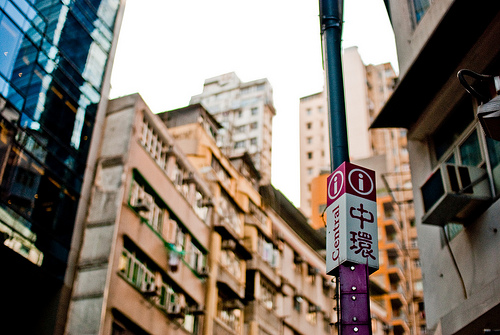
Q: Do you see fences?
A: No, there are no fences.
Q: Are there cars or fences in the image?
A: No, there are no fences or cars.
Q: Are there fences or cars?
A: No, there are no fences or cars.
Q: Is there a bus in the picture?
A: No, there are no buses.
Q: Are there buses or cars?
A: No, there are no buses or cars.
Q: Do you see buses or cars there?
A: No, there are no buses or cars.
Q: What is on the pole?
A: The sign is on the pole.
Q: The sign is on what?
A: The sign is on the pole.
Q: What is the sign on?
A: The sign is on the pole.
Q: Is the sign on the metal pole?
A: Yes, the sign is on the pole.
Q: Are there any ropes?
A: No, there are no ropes.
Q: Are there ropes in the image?
A: No, there are no ropes.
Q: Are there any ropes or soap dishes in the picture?
A: No, there are no ropes or soap dishes.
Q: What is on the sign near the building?
A: The symbol is on the sign.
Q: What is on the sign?
A: The symbol is on the sign.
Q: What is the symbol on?
A: The symbol is on the sign.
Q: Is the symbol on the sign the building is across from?
A: Yes, the symbol is on the sign.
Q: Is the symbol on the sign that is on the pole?
A: Yes, the symbol is on the sign.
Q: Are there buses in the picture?
A: No, there are no buses.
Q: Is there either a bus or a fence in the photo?
A: No, there are no buses or fences.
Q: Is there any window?
A: Yes, there are windows.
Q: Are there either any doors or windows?
A: Yes, there are windows.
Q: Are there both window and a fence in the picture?
A: No, there are windows but no fences.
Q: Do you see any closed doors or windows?
A: Yes, there are closed windows.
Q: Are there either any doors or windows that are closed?
A: Yes, the windows are closed.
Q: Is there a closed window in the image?
A: Yes, there are closed windows.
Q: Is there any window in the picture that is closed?
A: Yes, there are windows that are closed.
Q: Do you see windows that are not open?
A: Yes, there are closed windows.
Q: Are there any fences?
A: No, there are no fences.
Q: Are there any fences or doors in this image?
A: No, there are no fences or doors.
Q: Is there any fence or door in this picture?
A: No, there are no fences or doors.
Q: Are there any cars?
A: No, there are no cars.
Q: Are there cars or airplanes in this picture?
A: No, there are no cars or airplanes.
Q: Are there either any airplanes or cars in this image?
A: No, there are no cars or airplanes.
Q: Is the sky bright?
A: Yes, the sky is bright.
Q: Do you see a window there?
A: Yes, there is a window.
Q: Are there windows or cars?
A: Yes, there is a window.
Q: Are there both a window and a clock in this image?
A: No, there is a window but no clocks.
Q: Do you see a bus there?
A: No, there are no buses.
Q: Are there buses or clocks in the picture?
A: No, there are no buses or clocks.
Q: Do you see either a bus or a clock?
A: No, there are no buses or clocks.